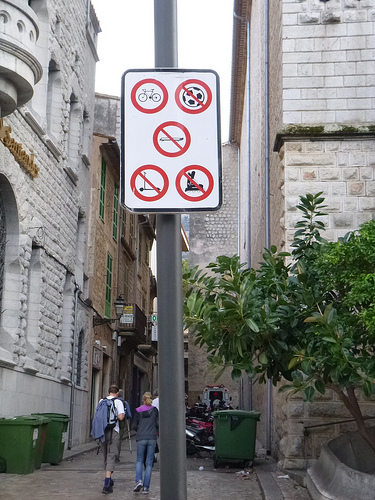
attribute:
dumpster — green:
[208, 406, 259, 469]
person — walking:
[92, 384, 130, 493]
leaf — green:
[242, 315, 261, 336]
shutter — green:
[97, 160, 108, 221]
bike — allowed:
[184, 408, 215, 465]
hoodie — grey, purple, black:
[129, 404, 164, 440]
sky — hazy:
[92, 2, 232, 135]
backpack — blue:
[99, 395, 122, 425]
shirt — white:
[98, 396, 127, 432]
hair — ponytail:
[143, 391, 153, 405]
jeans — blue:
[134, 439, 157, 486]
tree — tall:
[175, 191, 375, 447]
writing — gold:
[0, 131, 42, 177]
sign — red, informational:
[118, 68, 220, 212]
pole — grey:
[155, 212, 187, 499]